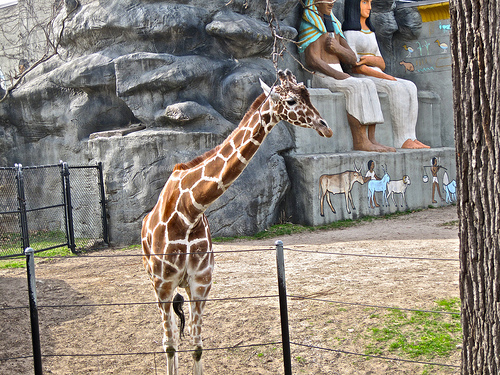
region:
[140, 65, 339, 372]
brown and cream giraffe standing in zoo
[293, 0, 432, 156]
statue of Egyptian man and woman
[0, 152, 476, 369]
metal wire and mesh fence around enclosure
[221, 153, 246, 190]
brown spot on off white giraffe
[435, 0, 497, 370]
grey bark of large tree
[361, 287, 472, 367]
small patch of grass on dirt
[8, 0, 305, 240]
large grey wall of rocks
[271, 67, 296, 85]
two horns on giraffe's head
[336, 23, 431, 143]
white gown on female statue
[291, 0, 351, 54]
blue and gold head dress on male statue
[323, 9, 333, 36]
The beard of the man in the statue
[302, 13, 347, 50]
The blue head dress of the man in the statue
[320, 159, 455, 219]
The painting on the wall behind the giraffe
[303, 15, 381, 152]
The man statue behind the giraffe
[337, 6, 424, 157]
The women statue that is behind the giraffe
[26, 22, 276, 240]
The rocky wall behind the giraffe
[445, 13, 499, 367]
The trunk of the tree next to the giraffee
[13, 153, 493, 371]
The fence that is surrounding the giraffe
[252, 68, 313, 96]
The giraffes ears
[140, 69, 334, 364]
A giraffe that is standing in a fenced in area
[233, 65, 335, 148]
large head of giraffe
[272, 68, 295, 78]
brown and black horns of giraffe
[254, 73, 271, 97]
white ear of giraffe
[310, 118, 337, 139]
brown and white nose of giraffe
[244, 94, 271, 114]
long brown mane of giraffe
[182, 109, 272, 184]
orange and white neck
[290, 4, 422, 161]
statues in back ground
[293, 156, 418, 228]
pictures of animals on wall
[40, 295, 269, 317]
long metal wire on fence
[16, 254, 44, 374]
black pole for fence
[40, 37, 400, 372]
this is at a zoo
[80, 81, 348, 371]
this is a giraffe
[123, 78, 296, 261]
the giraffe is in captivity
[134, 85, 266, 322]
the giraffe is very tall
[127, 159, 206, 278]
the giraffe is spotted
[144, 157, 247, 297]
the giraffe is brown and white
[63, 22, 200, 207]
these are rocks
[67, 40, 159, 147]
the wall is made of stone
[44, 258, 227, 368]
this is a wire fence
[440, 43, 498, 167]
this is a tree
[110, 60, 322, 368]
giraffe in the pen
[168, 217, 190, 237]
spot on the giraffe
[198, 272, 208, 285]
spot on the giraffe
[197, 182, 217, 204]
spot on the giraffe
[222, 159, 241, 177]
spot on the giraffe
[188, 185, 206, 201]
spot on the giraffe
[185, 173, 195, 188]
spot on the giraffe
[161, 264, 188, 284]
spot on the giraffe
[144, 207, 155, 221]
spot on the giraffe